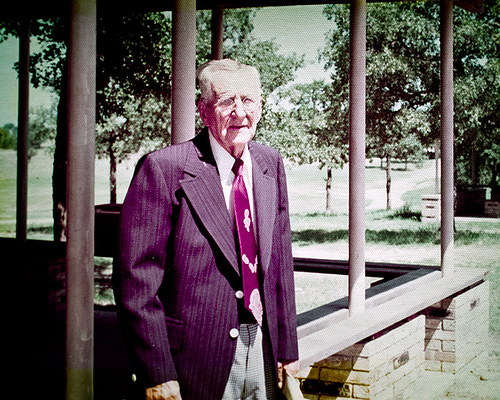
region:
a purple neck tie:
[231, 159, 262, 326]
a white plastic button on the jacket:
[235, 289, 244, 299]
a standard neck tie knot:
[231, 158, 246, 175]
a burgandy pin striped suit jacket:
[112, 128, 299, 398]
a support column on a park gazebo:
[64, 3, 96, 398]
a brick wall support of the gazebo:
[425, 278, 489, 374]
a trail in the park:
[365, 161, 440, 211]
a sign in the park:
[418, 192, 439, 227]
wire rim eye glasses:
[201, 93, 261, 113]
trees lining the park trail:
[286, 1, 498, 193]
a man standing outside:
[83, 31, 387, 384]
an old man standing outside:
[105, 47, 399, 394]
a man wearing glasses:
[150, 36, 227, 164]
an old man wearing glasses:
[175, 64, 290, 180]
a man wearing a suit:
[151, 82, 338, 360]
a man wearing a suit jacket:
[124, 95, 285, 398]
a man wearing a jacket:
[141, 100, 279, 399]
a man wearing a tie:
[115, 77, 299, 390]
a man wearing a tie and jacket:
[164, 102, 337, 373]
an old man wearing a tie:
[154, 112, 259, 327]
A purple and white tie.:
[228, 160, 263, 327]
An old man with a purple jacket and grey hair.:
[112, 58, 299, 399]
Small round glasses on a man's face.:
[201, 97, 264, 109]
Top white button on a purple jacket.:
[232, 289, 245, 301]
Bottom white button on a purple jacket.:
[228, 326, 240, 338]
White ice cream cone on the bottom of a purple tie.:
[248, 285, 265, 327]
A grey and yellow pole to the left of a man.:
[66, 0, 94, 399]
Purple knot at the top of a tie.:
[230, 158, 245, 174]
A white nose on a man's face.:
[231, 95, 248, 120]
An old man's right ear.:
[196, 100, 212, 127]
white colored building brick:
[352, 351, 387, 369]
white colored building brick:
[387, 342, 405, 355]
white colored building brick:
[319, 354, 351, 370]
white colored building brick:
[320, 365, 370, 380]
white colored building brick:
[421, 326, 454, 338]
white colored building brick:
[427, 338, 441, 349]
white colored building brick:
[442, 338, 455, 349]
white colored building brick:
[423, 350, 456, 360]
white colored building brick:
[426, 359, 441, 370]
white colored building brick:
[441, 360, 454, 372]